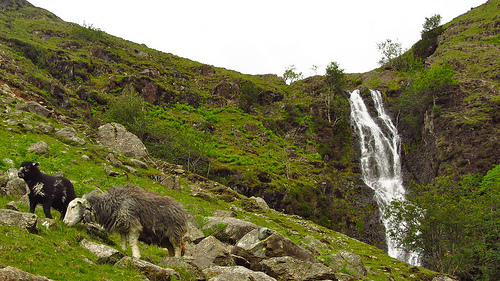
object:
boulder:
[90, 121, 157, 163]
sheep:
[56, 180, 198, 266]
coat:
[83, 185, 191, 246]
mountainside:
[0, 0, 459, 281]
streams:
[370, 85, 429, 269]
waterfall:
[345, 78, 426, 275]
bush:
[372, 36, 409, 77]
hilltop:
[443, 0, 499, 29]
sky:
[32, 0, 489, 86]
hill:
[0, 0, 500, 182]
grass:
[0, 0, 500, 281]